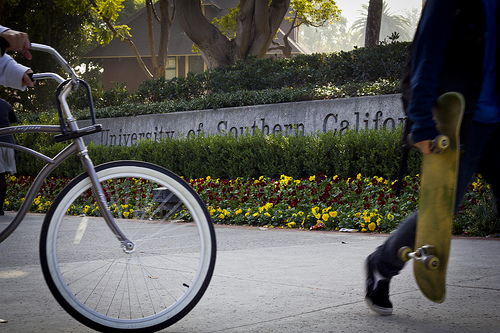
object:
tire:
[35, 158, 220, 333]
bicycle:
[4, 41, 217, 328]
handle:
[20, 39, 80, 80]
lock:
[47, 74, 106, 146]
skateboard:
[393, 90, 466, 305]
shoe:
[362, 250, 397, 315]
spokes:
[121, 256, 135, 322]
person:
[363, 0, 496, 317]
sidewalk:
[1, 210, 500, 333]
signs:
[95, 106, 416, 151]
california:
[316, 107, 406, 141]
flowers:
[319, 212, 332, 222]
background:
[0, 0, 499, 333]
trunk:
[170, 0, 291, 101]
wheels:
[430, 134, 451, 153]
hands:
[403, 127, 440, 156]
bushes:
[353, 41, 409, 95]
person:
[0, 24, 40, 216]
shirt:
[397, 0, 497, 145]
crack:
[204, 281, 366, 332]